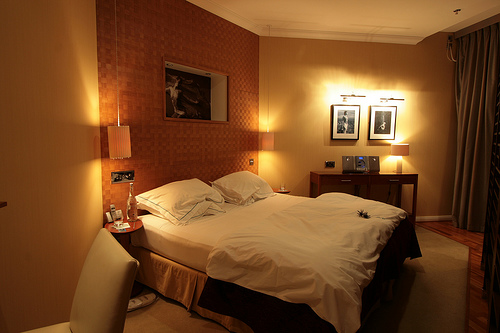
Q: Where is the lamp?
A: On the table.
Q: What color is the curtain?
A: Green.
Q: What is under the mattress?
A: A bed skirt.